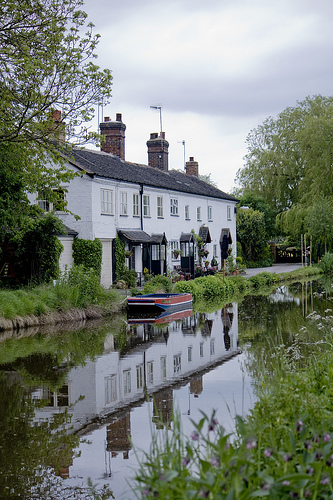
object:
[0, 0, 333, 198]
sky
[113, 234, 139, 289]
ivy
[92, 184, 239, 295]
wall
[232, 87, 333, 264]
tree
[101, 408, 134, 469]
chimney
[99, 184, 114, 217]
window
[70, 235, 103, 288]
ivy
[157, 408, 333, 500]
plant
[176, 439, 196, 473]
flowers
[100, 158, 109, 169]
tiles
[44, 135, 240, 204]
roof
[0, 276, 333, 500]
water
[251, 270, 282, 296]
bushes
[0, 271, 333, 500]
river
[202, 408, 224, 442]
flowers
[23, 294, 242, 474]
building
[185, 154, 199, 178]
chimney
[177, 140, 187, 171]
antenna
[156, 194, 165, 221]
window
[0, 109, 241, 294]
building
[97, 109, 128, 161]
chimney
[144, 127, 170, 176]
chimneys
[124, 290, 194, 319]
boat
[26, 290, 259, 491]
reflection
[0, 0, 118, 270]
tree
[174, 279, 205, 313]
bushes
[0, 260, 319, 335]
river bank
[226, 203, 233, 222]
windows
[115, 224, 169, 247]
overhang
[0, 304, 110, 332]
grass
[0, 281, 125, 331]
bank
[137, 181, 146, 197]
gutter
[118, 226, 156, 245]
awning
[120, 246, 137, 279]
door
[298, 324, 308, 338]
flowers